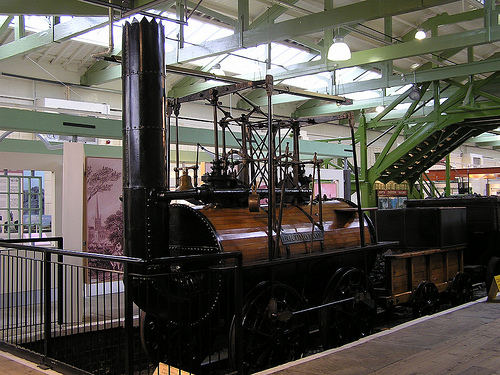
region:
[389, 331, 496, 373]
Pathway is grey color.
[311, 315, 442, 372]
White lines in pathway.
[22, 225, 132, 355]
Rail is black color.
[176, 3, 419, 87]
Rod is grey color.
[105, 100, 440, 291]
Engine is brown and black color.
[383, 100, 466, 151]
Steps is green color,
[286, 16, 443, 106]
Lights are hanging from roof.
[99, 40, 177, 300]
Chimney is black color.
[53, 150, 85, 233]
Wall is white color.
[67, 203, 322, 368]
Train is in shed.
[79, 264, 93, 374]
This is a metal bar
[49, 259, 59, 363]
This is a metal bar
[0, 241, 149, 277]
This is a metal bar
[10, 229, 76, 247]
This is a metal bar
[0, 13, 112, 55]
This is a metal bar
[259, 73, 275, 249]
This is a metal bar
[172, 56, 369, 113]
This is a metal bar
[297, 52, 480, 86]
This is a metal bar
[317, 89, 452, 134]
This is a metal bar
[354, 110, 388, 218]
This is a metal bar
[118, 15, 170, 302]
one large black metal pipe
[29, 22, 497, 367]
metal and wooden train in a museum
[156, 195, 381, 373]
front of wooden train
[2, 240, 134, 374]
black indoor metal railing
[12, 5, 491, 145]
green wooden beams on ceiling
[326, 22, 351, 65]
one metal ceiling lamp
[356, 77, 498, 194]
stairs with green railing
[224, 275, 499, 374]
black train wheels at platform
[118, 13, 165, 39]
zigzag pattern on top of metal pipe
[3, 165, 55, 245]
square design metal work over window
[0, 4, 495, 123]
green beams on ceiling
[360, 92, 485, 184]
underside of stairwell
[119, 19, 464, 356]
antique train on display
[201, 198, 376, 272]
curved wood of train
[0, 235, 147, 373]
black poles on railing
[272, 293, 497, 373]
white line on edge of platform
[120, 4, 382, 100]
sun in skylight windows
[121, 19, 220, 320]
black pipe of antique train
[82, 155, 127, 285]
picture in wood frame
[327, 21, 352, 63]
glowing light on pole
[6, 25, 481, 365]
Vintage train on display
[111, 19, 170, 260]
Black metal train funnel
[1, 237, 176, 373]
Black metal fence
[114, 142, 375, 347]
Train engine on display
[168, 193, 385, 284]
Metal and wooden train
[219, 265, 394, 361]
Metal train wheel and piston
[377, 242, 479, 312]
Wood and metal train coal bin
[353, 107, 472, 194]
Grey and black staircase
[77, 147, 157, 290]
Edge of wall painting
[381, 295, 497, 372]
Light tan concrete tiled sidewalk